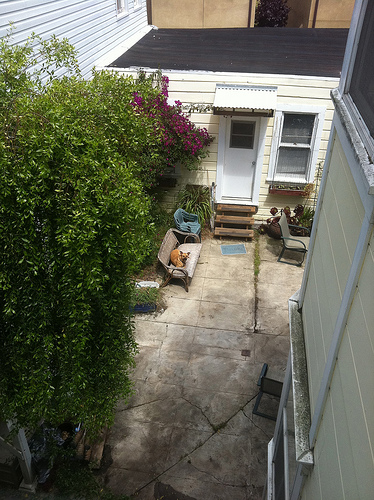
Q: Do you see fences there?
A: No, there are no fences.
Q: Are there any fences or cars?
A: No, there are no fences or cars.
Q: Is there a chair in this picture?
A: Yes, there is a chair.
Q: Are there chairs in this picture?
A: Yes, there is a chair.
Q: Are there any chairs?
A: Yes, there is a chair.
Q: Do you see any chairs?
A: Yes, there is a chair.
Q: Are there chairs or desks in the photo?
A: Yes, there is a chair.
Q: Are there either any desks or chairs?
A: Yes, there is a chair.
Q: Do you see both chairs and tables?
A: No, there is a chair but no tables.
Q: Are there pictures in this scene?
A: No, there are no pictures.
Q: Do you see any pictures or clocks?
A: No, there are no pictures or clocks.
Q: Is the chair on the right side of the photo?
A: Yes, the chair is on the right of the image.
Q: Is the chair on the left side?
A: No, the chair is on the right of the image.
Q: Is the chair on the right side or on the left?
A: The chair is on the right of the image.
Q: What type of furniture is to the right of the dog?
A: The piece of furniture is a chair.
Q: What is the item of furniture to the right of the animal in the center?
A: The piece of furniture is a chair.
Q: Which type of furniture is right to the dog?
A: The piece of furniture is a chair.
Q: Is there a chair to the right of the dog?
A: Yes, there is a chair to the right of the dog.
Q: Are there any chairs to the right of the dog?
A: Yes, there is a chair to the right of the dog.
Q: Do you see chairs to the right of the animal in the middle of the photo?
A: Yes, there is a chair to the right of the dog.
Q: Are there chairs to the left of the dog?
A: No, the chair is to the right of the dog.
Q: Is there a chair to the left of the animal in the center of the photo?
A: No, the chair is to the right of the dog.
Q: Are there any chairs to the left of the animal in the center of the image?
A: No, the chair is to the right of the dog.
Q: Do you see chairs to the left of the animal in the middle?
A: No, the chair is to the right of the dog.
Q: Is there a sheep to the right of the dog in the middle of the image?
A: No, there is a chair to the right of the dog.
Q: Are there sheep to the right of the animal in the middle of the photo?
A: No, there is a chair to the right of the dog.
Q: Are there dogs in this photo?
A: Yes, there is a dog.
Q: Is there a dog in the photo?
A: Yes, there is a dog.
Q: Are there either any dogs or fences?
A: Yes, there is a dog.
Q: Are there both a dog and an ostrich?
A: No, there is a dog but no ostriches.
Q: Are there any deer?
A: No, there are no deer.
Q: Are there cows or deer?
A: No, there are no deer or cows.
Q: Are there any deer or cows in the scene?
A: No, there are no deer or cows.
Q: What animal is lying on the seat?
A: The dog is lying on the seat.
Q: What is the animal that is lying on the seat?
A: The animal is a dog.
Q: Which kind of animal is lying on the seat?
A: The animal is a dog.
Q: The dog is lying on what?
A: The dog is lying on the seat.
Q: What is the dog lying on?
A: The dog is lying on the seat.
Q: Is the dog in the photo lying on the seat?
A: Yes, the dog is lying on the seat.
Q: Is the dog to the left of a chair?
A: Yes, the dog is to the left of a chair.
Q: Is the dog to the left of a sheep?
A: No, the dog is to the left of a chair.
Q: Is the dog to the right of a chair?
A: No, the dog is to the left of a chair.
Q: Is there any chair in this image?
A: Yes, there is a chair.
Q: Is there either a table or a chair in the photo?
A: Yes, there is a chair.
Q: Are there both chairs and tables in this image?
A: No, there is a chair but no tables.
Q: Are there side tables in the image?
A: No, there are no side tables.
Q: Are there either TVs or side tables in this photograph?
A: No, there are no side tables or tvs.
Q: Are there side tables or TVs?
A: No, there are no side tables or tvs.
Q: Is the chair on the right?
A: Yes, the chair is on the right of the image.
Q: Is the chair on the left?
A: No, the chair is on the right of the image.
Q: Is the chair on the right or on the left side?
A: The chair is on the right of the image.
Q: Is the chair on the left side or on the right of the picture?
A: The chair is on the right of the image.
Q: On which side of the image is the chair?
A: The chair is on the right of the image.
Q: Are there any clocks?
A: No, there are no clocks.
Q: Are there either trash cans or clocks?
A: No, there are no clocks or trash cans.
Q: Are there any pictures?
A: No, there are no pictures.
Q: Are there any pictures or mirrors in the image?
A: No, there are no pictures or mirrors.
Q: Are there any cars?
A: No, there are no cars.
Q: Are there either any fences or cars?
A: No, there are no cars or fences.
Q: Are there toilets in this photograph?
A: No, there are no toilets.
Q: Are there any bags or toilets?
A: No, there are no toilets or bags.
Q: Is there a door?
A: Yes, there is a door.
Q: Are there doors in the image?
A: Yes, there is a door.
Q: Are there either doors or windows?
A: Yes, there is a door.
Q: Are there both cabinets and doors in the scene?
A: No, there is a door but no cabinets.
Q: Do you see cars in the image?
A: No, there are no cars.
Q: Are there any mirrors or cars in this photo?
A: No, there are no cars or mirrors.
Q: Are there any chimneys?
A: No, there are no chimneys.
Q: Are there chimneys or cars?
A: No, there are no chimneys or cars.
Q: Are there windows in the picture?
A: Yes, there is a window.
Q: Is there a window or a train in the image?
A: Yes, there is a window.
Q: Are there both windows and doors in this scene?
A: Yes, there are both a window and a door.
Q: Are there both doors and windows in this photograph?
A: Yes, there are both a window and a door.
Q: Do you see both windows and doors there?
A: Yes, there are both a window and a door.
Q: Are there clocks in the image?
A: No, there are no clocks.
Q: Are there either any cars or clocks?
A: No, there are no clocks or cars.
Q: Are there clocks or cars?
A: No, there are no clocks or cars.